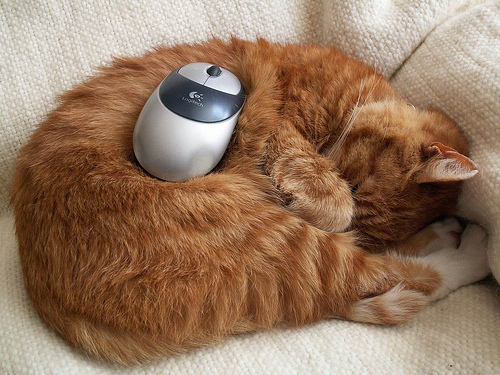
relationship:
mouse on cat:
[133, 61, 243, 181] [17, 37, 490, 362]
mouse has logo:
[133, 61, 243, 181] [183, 90, 206, 107]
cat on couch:
[17, 37, 490, 362] [0, 1, 497, 374]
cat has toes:
[17, 37, 490, 362] [429, 218, 488, 280]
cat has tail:
[17, 37, 490, 362] [24, 257, 181, 365]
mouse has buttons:
[133, 61, 243, 181] [181, 61, 240, 93]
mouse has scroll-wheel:
[133, 61, 243, 181] [208, 64, 221, 76]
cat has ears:
[17, 37, 490, 362] [424, 145, 478, 183]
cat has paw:
[17, 37, 490, 362] [280, 138, 354, 229]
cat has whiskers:
[17, 37, 490, 362] [332, 64, 383, 157]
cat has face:
[17, 37, 490, 362] [340, 130, 416, 235]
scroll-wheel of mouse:
[208, 64, 221, 76] [133, 61, 243, 181]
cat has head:
[17, 37, 490, 362] [349, 101, 468, 236]